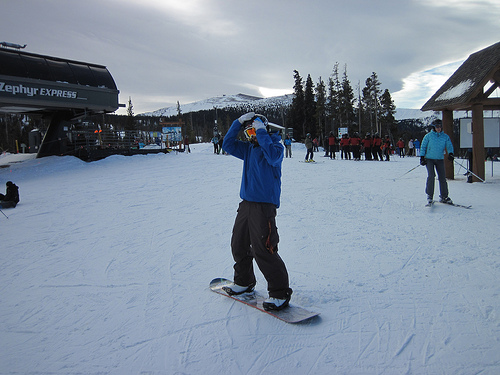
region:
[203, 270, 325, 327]
a black snowboard under the man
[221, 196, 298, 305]
a pair of gray pants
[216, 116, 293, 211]
a blue coat on the person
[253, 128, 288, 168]
the arm of a person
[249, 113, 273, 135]
a gray glove on the person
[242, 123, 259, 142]
a pair of orange goggles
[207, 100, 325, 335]
a person on the snowboard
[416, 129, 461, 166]
a pale blue coat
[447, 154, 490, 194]
a ski pole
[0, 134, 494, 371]
white snow on the ground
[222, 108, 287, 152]
Fixing gear on head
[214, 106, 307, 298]
Blue jacket gray pants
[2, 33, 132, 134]
Travel by Zephyr express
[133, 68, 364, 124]
Snow capped mountains in the distance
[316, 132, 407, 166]
All wearing red outfits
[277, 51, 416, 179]
Pine trees standing tall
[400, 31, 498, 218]
A small bit of shelter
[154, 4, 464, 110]
Cold weather clouds abound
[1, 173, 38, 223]
Sitting in the snow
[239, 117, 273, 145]
Brightly colored ski goggles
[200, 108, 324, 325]
A man standing on skiing board.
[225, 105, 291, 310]
A person holding his head.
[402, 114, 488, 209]
A person moving on snow using skiing board.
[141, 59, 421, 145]
Trees in the background of the skiing track.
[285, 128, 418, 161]
People standing in a group.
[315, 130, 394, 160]
Skiers in similar uniform on the skiing track.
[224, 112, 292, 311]
Skier in a blue top.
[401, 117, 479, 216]
Skier using skiing sticks to move.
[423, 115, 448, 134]
Skier with helmet on his head.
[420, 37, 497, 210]
Grass thashed and wooden shelter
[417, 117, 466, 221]
Skiier in a pale blue coat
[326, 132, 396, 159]
Large crowd of people in matching red jackets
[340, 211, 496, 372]
Skii tracks in the snow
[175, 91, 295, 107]
Snow covered mountain top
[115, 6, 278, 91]
White cloudy skies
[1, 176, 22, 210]
Kid sitting on the snow covered ground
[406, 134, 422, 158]
Two people standing side by side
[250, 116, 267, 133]
Grey left hand glove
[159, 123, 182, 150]
Large posted sign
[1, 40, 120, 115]
Zephyr Express chair lift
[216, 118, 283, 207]
person is wearing blue jacket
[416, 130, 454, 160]
person is wearing light blue jacket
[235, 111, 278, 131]
person is fixing helmet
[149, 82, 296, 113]
snow is on mountain top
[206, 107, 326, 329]
person is standing on snow board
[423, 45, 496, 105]
roof has snow on top of it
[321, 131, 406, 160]
group of people are in back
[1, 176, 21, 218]
person sitting on snow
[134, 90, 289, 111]
mountains are behind the trees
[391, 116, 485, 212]
person is standing on skii boards